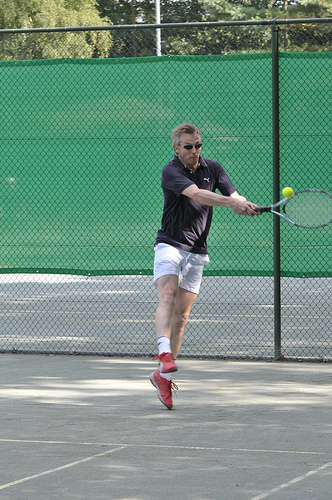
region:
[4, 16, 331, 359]
tall grey chain link fence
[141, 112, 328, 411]
man playing tennis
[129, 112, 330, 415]
man wearing red tennis shoes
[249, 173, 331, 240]
grey and black tennis racket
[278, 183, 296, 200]
yellow tennis ball midair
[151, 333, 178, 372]
black and white socks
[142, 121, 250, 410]
man wearing black polo shirt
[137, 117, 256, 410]
man wearing dark sunglasses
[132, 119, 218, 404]
man wearing white shorts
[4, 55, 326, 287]
green barrier tied on fence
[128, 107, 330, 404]
a man tries to hit a tennis ball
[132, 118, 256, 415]
a man is holding a tennis racket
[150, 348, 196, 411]
red shoes cover a man's feet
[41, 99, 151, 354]
a black wire fence stand behind a man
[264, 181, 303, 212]
a bright green tennis ball flies through the air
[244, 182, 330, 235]
a tennis racket strikes a tennis ball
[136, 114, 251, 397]
a man is wearing a blue shirt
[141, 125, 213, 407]
a man is wearing white shorts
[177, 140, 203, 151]
sunglasses rest on man's nose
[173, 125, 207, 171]
gray hair tops a man's head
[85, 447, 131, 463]
white line on tennis court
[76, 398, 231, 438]
gray asphalt on tennis court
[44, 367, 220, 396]
light reflecting on tennis court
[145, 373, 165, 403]
white sole on red sneaker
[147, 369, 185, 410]
red sneaker with laces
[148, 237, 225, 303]
man wearing white shorts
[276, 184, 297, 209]
yellow tennis ball in flight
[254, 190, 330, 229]
tennis racquet with black trim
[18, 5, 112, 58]
large green tree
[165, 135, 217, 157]
man wearing sun glasses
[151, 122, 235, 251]
A man wearing a blue shirt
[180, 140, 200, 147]
A man is wearing dark glasses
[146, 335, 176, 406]
A man is wearing red and white shoes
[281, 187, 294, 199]
A round yellow tennis ball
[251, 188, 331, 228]
A black and silver tennis rack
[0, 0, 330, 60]
A line of green trees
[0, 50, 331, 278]
A green tennis court guard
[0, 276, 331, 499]
A tennis court with white lines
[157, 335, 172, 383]
A pair of white soxs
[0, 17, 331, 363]
A metal wire fence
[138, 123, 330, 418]
a man about to hit the ball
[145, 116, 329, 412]
a man hitting a two hand backhand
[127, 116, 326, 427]
a man barely touching the ground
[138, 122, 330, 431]
a player nearly airborn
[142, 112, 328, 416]
a man in red shoes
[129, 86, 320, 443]
a man hitting a yellow ball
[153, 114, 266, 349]
a man wearing sunglasses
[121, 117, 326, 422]
a man in white shorts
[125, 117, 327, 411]
a man in a black shirt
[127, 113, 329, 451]
a player hitting a backhand